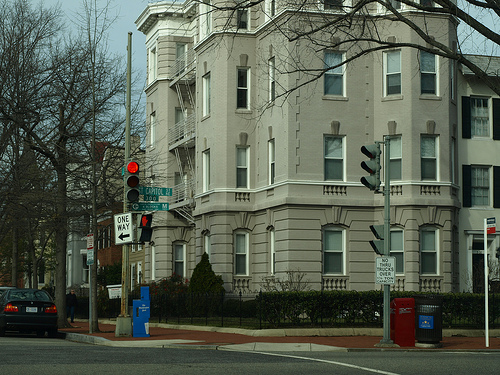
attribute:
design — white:
[128, 0, 201, 30]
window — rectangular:
[323, 222, 344, 274]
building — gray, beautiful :
[118, 0, 498, 321]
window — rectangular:
[384, 132, 404, 183]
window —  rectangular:
[471, 166, 493, 212]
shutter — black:
[461, 163, 474, 206]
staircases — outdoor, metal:
[172, 37, 199, 218]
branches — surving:
[237, 6, 498, 98]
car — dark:
[1, 277, 62, 340]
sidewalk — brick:
[72, 315, 499, 355]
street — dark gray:
[6, 343, 495, 373]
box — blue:
[130, 277, 157, 338]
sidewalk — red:
[81, 330, 382, 346]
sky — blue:
[57, 4, 129, 51]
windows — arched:
[162, 219, 451, 280]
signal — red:
[122, 155, 138, 176]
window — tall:
[315, 221, 349, 277]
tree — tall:
[50, 103, 73, 337]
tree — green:
[184, 246, 224, 318]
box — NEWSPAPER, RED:
[395, 299, 414, 350]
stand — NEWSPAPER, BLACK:
[417, 302, 440, 344]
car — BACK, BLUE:
[8, 286, 55, 334]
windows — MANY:
[172, 127, 447, 194]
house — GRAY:
[143, 8, 481, 287]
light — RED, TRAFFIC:
[121, 153, 141, 200]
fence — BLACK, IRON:
[251, 299, 379, 322]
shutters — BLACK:
[462, 100, 474, 140]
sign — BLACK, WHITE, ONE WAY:
[96, 213, 139, 243]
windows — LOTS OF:
[196, 133, 444, 176]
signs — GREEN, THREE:
[126, 180, 176, 221]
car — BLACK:
[6, 278, 56, 334]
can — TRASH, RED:
[391, 300, 413, 342]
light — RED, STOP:
[116, 153, 138, 204]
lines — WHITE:
[296, 349, 345, 373]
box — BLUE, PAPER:
[133, 282, 156, 332]